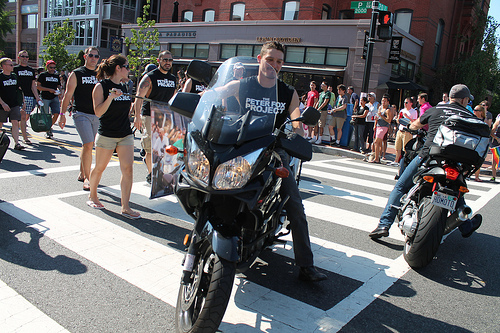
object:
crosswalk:
[2, 155, 499, 330]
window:
[277, 2, 298, 22]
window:
[225, 3, 249, 22]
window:
[197, 9, 218, 20]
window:
[178, 7, 195, 22]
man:
[134, 49, 183, 184]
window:
[322, 43, 357, 69]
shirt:
[236, 73, 294, 138]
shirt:
[415, 100, 476, 159]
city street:
[7, 95, 498, 332]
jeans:
[379, 155, 469, 228]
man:
[197, 33, 330, 281]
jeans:
[265, 153, 317, 269]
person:
[12, 48, 44, 144]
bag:
[429, 109, 493, 170]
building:
[38, 0, 140, 68]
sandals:
[86, 198, 109, 210]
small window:
[427, 16, 446, 70]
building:
[161, 0, 488, 104]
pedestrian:
[86, 53, 141, 221]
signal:
[373, 9, 391, 24]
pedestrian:
[59, 47, 109, 191]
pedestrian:
[370, 95, 390, 162]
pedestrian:
[393, 99, 420, 163]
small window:
[188, 56, 277, 144]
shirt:
[419, 101, 429, 117]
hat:
[446, 83, 476, 98]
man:
[368, 80, 485, 246]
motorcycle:
[390, 124, 480, 266]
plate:
[432, 187, 464, 212]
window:
[393, 6, 413, 33]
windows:
[86, 8, 101, 40]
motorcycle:
[169, 55, 321, 332]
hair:
[157, 49, 173, 61]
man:
[415, 92, 432, 130]